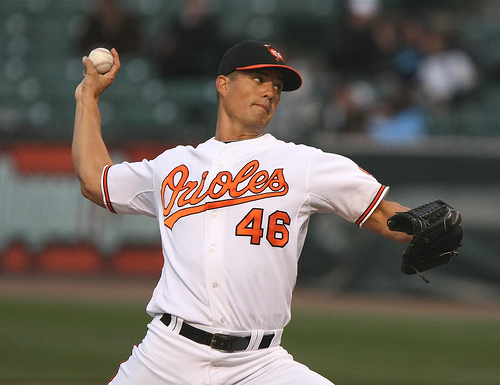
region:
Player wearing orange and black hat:
[204, 31, 306, 140]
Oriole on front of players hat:
[262, 41, 291, 64]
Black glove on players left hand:
[376, 180, 479, 289]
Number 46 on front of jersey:
[229, 203, 297, 259]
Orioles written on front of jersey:
[147, 148, 299, 229]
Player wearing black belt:
[138, 299, 304, 358]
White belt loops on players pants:
[244, 325, 288, 353]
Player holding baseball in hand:
[67, 37, 127, 101]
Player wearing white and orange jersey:
[97, 126, 396, 335]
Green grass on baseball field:
[28, 307, 108, 345]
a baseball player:
[15, 32, 443, 334]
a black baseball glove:
[373, 185, 498, 314]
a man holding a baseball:
[59, 20, 320, 218]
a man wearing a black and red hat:
[181, 39, 326, 142]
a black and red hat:
[201, 16, 340, 101]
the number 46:
[211, 198, 311, 258]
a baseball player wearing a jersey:
[53, 27, 401, 347]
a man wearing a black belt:
[73, 36, 364, 366]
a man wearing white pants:
[84, 43, 339, 383]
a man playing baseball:
[94, 44, 371, 334]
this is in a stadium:
[11, 17, 458, 342]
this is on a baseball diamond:
[60, 26, 427, 334]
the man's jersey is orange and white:
[155, 153, 345, 368]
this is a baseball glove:
[387, 201, 469, 299]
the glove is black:
[384, 185, 491, 317]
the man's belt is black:
[154, 295, 268, 352]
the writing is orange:
[151, 178, 293, 267]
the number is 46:
[237, 197, 329, 277]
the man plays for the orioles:
[137, 143, 406, 353]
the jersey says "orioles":
[165, 153, 346, 278]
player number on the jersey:
[235, 207, 290, 247]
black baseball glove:
[387, 200, 460, 274]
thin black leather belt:
[159, 315, 280, 347]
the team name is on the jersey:
[162, 160, 288, 228]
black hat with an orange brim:
[217, 38, 300, 90]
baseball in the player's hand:
[80, 48, 119, 93]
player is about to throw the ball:
[71, 40, 460, 383]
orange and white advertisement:
[2, 151, 167, 273]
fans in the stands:
[88, 8, 495, 131]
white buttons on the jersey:
[207, 212, 224, 308]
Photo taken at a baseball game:
[6, 8, 491, 374]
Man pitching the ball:
[50, 40, 461, 375]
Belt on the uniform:
[145, 310, 280, 355]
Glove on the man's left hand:
[390, 190, 470, 280]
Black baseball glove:
[380, 191, 470, 286]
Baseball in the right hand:
[77, 35, 119, 75]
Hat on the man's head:
[210, 35, 307, 97]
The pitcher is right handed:
[65, 26, 190, 241]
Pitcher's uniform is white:
[87, 135, 394, 381]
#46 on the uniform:
[230, 207, 291, 252]